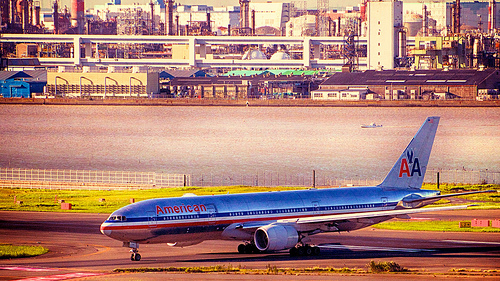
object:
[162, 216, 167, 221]
windows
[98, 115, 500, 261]
airplane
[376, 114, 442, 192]
tail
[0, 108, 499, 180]
water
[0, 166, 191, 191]
fence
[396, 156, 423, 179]
logo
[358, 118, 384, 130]
boat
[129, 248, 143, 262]
wheel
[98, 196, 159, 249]
front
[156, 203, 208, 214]
word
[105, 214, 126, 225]
windsheild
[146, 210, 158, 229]
door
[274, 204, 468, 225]
wing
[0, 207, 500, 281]
run way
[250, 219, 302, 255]
engine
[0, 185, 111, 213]
green grass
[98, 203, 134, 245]
nose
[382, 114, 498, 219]
back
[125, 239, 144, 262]
landing gear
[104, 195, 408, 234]
side